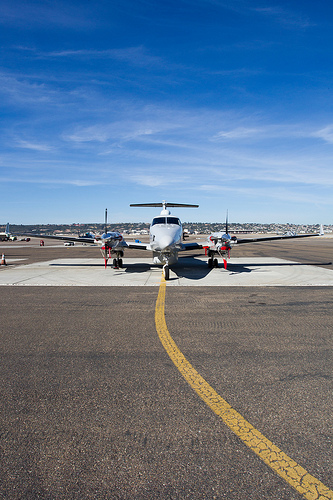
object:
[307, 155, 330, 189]
clouds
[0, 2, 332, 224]
sky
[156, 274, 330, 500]
line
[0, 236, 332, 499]
ground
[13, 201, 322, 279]
plane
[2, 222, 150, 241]
hill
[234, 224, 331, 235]
houses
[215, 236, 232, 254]
engine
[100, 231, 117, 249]
engine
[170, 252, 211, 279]
shadow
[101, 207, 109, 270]
propeller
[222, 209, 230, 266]
propeller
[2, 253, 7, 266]
cone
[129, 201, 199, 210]
tail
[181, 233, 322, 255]
wing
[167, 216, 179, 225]
window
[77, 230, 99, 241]
helicopter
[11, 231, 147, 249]
wing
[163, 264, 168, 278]
wheel